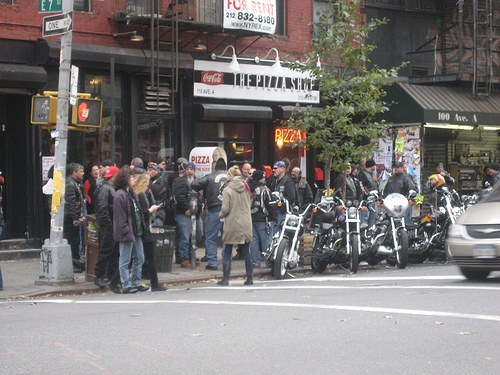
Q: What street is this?
A: East 7th.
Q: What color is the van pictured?
A: Gold.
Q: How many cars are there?
A: One.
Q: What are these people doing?
A: Standing.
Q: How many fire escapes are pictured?
A: Two.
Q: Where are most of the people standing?
A: On the sidewalk.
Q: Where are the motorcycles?
A: Parked on the street.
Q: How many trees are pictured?
A: One.